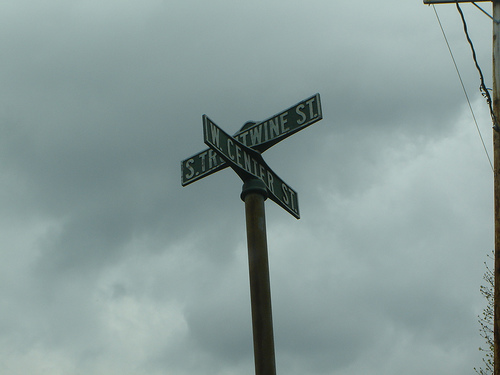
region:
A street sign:
[131, 80, 362, 252]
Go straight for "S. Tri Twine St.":
[157, 97, 379, 184]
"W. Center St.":
[173, 110, 349, 235]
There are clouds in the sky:
[21, 11, 433, 91]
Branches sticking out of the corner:
[413, 192, 499, 349]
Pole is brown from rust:
[230, 190, 308, 374]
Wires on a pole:
[424, 3, 499, 138]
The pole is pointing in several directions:
[128, 68, 377, 373]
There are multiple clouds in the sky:
[5, 10, 498, 315]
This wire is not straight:
[452, 3, 497, 98]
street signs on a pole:
[140, 41, 397, 343]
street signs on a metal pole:
[147, 40, 407, 355]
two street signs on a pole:
[132, 36, 369, 369]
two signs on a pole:
[132, 77, 369, 344]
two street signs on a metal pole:
[167, 58, 350, 355]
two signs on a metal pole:
[135, 62, 382, 365]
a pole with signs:
[107, 48, 379, 373]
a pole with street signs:
[137, 87, 383, 364]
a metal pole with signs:
[98, 58, 415, 373]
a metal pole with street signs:
[128, 52, 390, 374]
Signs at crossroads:
[172, 94, 327, 229]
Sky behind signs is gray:
[10, 11, 492, 369]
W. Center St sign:
[199, 125, 313, 210]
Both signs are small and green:
[181, 98, 334, 193]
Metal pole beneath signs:
[237, 183, 292, 373]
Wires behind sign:
[446, 45, 493, 175]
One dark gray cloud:
[12, 63, 470, 182]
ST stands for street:
[274, 181, 305, 212]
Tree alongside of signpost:
[481, 244, 496, 373]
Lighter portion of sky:
[93, 300, 209, 368]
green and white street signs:
[182, 111, 309, 221]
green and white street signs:
[244, 101, 329, 148]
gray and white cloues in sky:
[21, 21, 133, 85]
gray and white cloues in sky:
[20, 66, 144, 187]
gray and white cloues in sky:
[20, 173, 147, 300]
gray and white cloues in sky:
[124, 229, 218, 313]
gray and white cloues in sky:
[105, 29, 250, 106]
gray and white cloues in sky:
[347, 33, 454, 117]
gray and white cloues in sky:
[307, 175, 465, 233]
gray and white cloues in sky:
[290, 249, 432, 326]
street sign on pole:
[121, 33, 417, 373]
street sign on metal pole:
[140, 31, 380, 341]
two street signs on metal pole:
[158, 43, 370, 361]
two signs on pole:
[103, 38, 424, 337]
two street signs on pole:
[139, 66, 373, 373]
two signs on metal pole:
[132, 70, 363, 373]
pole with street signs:
[176, 59, 410, 373]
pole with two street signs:
[111, 55, 376, 374]